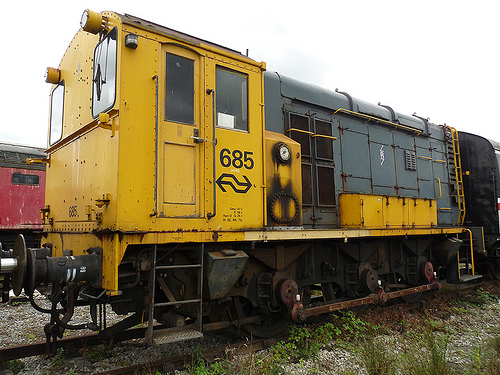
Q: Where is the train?
A: On the train tracks.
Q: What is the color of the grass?
A: Green.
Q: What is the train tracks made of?
A: Gravel and metal.